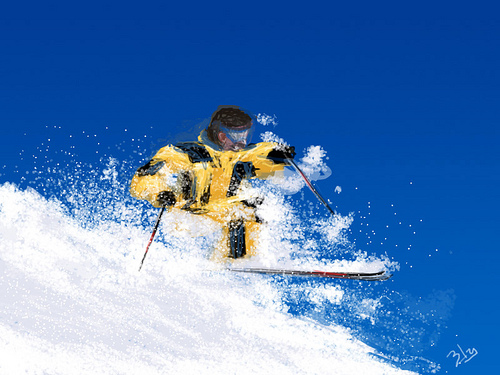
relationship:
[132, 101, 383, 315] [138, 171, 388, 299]
person on skiing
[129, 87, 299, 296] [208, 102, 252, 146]
man has hair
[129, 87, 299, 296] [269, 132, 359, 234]
man holding ski pole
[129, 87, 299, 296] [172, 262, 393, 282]
man wearing skis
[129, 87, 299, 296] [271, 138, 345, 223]
man holding ski pole